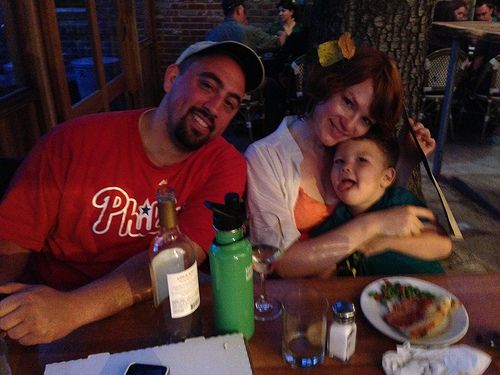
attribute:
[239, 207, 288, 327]
glass — clear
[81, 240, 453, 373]
dining table — brown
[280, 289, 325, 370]
glass cup — small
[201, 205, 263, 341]
beverage bottle — green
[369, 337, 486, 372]
napkin — white, used, paper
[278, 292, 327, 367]
glass — clear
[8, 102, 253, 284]
shirt — red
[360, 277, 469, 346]
plate — circular, white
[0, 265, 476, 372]
table — brown, wooden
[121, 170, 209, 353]
bottle — empty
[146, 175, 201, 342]
bottle — empty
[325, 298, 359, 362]
salt shaker — glass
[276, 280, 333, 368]
glass — clear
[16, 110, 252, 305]
shirt — red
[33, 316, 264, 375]
box — white, cardboard